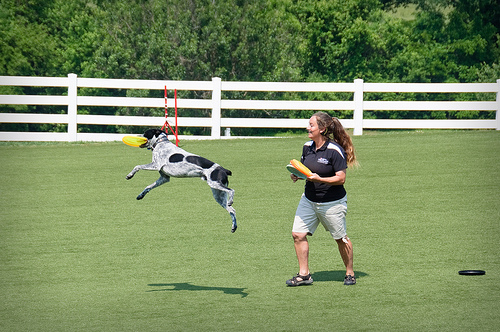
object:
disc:
[458, 269, 486, 275]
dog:
[125, 128, 237, 233]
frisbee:
[122, 136, 149, 148]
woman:
[283, 111, 362, 287]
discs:
[286, 157, 313, 177]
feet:
[285, 273, 314, 286]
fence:
[0, 73, 500, 143]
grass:
[0, 128, 498, 332]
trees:
[0, 0, 499, 137]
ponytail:
[330, 117, 361, 169]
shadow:
[146, 282, 250, 298]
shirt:
[300, 140, 348, 202]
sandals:
[285, 273, 314, 287]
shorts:
[291, 192, 348, 241]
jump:
[160, 85, 180, 147]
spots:
[168, 153, 185, 163]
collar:
[151, 136, 168, 150]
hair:
[310, 110, 363, 169]